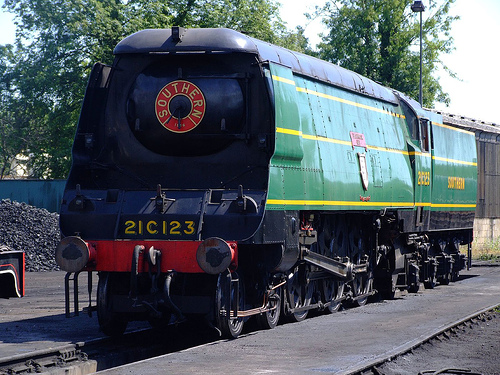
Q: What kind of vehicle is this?
A: A train.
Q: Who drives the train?
A: The conductor.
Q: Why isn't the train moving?
A: Because it is parked.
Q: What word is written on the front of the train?
A: Southern.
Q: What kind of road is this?
A: A railroad.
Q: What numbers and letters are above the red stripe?
A: 21C123.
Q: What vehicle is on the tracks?
A: Train.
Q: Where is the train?
A: On the rails.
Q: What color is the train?
A: Green.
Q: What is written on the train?
A: Southern.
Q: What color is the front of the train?
A: Black.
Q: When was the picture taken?
A: Daytime.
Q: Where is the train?
A: On the track.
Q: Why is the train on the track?
A: Parked.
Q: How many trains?
A: 1.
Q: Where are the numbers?
A: The front of the train.